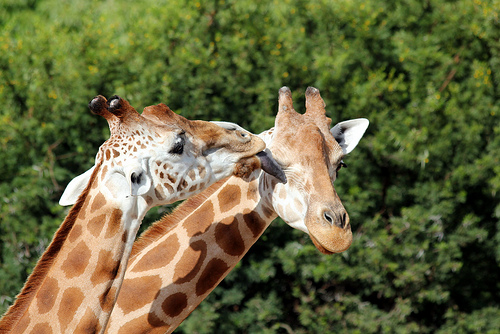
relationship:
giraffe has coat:
[0, 79, 294, 334] [44, 201, 123, 320]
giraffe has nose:
[0, 79, 294, 334] [223, 121, 264, 151]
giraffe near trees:
[0, 79, 294, 334] [150, 16, 468, 86]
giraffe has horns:
[0, 79, 294, 334] [83, 92, 136, 122]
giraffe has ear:
[0, 79, 294, 334] [119, 160, 158, 197]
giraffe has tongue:
[0, 79, 294, 334] [260, 150, 288, 184]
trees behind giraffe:
[150, 16, 468, 86] [0, 79, 294, 334]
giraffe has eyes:
[0, 79, 294, 334] [168, 131, 196, 156]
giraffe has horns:
[248, 94, 359, 272] [273, 86, 326, 122]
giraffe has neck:
[248, 94, 359, 272] [165, 209, 253, 266]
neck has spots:
[165, 209, 253, 266] [182, 206, 246, 251]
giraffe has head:
[0, 79, 294, 334] [77, 99, 279, 209]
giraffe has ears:
[0, 79, 294, 334] [67, 164, 167, 195]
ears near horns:
[67, 164, 167, 195] [83, 92, 136, 122]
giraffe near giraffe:
[0, 79, 294, 334] [248, 94, 359, 272]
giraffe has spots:
[248, 94, 359, 272] [182, 206, 246, 251]